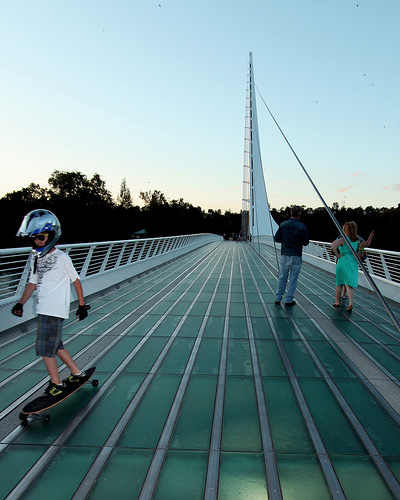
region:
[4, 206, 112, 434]
A boy on skateboard.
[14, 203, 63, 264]
A boy wearing helmet while skateboarding.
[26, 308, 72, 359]
Boy wearing plaid shorts.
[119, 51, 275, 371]
Suspension on a bridge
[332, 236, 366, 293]
Woman wearing a green dress.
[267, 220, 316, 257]
Man wearing blue shirt.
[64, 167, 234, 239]
Trees growing next to bridge.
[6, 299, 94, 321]
Boy wearing black gloves.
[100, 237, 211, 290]
Railing along side of bridge.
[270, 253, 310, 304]
Man wearing blue jeans.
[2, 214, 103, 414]
young boy skateboarding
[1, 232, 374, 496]
Steel bridge colored green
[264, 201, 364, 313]
people walking on the bridge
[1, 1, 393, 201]
clear blue sky above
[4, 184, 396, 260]
Tree landscape in the background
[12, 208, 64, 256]
boy wearing a helmet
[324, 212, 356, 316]
woman in blue dress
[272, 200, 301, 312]
man in blue jeans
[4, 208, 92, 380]
boy in shorts and t-shirt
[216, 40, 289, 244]
bridge structure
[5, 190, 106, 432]
boy on a black skateboard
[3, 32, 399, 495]
a bridge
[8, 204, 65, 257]
a shiny silver helmet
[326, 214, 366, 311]
a woman in a knee length green dress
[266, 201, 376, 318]
three people walking on the bridge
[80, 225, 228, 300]
a white guardrail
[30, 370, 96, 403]
yellow and black sneakers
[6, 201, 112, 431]
a kid skateboarding in a silver helmet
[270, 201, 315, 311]
a man in jeans and a blue shirt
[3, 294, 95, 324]
black athletic gloves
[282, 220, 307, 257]
Black shirt worn by man walking with woman.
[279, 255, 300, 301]
Blue jeans worn by man walking with woman.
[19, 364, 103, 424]
Skateboard boy is riding on.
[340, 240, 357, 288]
Greenish colored dress worn by woman walking.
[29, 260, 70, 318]
White t-shirt with black design worn by boy riding skateboard.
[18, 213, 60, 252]
Metallic colored helmet worn by boy riding skateboard.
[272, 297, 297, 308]
Black shoes worn by man walking with woman.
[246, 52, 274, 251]
Tall structure attached to pathway people are walking on.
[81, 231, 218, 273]
Side railing on left of photo.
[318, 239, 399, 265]
Side railing on right of photo.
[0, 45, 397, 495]
people on a bridge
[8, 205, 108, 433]
boy on skateboard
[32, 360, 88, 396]
black and yellow shoes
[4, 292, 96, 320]
boy wearing black fingerless gloves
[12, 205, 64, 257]
boy wearing large blue helmet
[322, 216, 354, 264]
woman's left hand on her hip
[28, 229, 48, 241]
boy wearing dark sunglasses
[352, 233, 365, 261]
woman has purse on her right shoulder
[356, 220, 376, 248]
woman pointing with her right hand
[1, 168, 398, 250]
dark trees in the distance